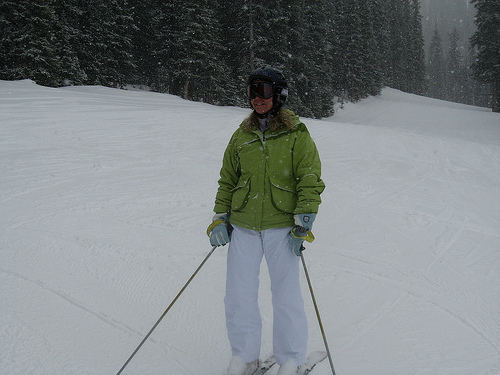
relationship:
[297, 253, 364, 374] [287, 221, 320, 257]
ski pole in hand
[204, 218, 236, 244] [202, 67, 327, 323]
glove on person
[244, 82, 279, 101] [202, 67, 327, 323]
mask on person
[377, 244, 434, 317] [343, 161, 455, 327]
tracks in snow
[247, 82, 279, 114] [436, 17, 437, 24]
mask for protection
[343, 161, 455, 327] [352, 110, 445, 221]
snow on ground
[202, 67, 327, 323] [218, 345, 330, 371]
woman on skis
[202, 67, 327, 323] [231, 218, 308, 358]
woman wears pants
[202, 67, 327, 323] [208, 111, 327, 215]
woman in jacket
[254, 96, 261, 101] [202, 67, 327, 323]
nose of person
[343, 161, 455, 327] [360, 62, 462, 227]
snow on hill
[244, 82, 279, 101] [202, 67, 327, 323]
mask on woman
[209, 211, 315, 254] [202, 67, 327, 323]
gloves on woman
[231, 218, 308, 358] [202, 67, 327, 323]
pants on woman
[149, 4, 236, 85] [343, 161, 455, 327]
trees with snow